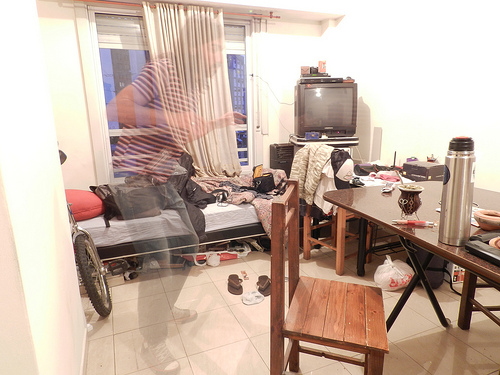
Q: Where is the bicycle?
A: Beside the wall.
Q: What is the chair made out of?
A: Wood.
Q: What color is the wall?
A: White.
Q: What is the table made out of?
A: Wood.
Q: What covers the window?
A: Curtains.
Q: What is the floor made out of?
A: Tile.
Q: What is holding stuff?
A: Table.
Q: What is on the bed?
A: Clothes.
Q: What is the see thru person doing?
A: Dancing.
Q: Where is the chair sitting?
A: On floor.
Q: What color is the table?
A: Brown.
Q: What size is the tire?
A: Small.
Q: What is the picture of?
A: Chair.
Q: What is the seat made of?
A: Wood.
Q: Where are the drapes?
A: Over the window.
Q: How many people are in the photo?
A: One.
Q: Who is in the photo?
A: A man.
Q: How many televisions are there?
A: One.